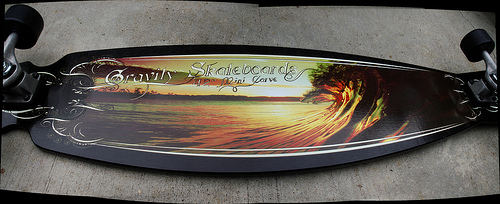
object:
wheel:
[459, 28, 495, 63]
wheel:
[0, 3, 45, 50]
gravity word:
[104, 67, 178, 86]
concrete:
[2, 3, 499, 203]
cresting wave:
[302, 62, 404, 153]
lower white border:
[43, 116, 473, 160]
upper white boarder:
[68, 53, 429, 94]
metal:
[2, 32, 41, 104]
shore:
[86, 90, 320, 104]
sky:
[85, 57, 338, 99]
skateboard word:
[183, 61, 292, 80]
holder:
[468, 50, 500, 110]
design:
[40, 53, 469, 158]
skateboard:
[3, 3, 496, 178]